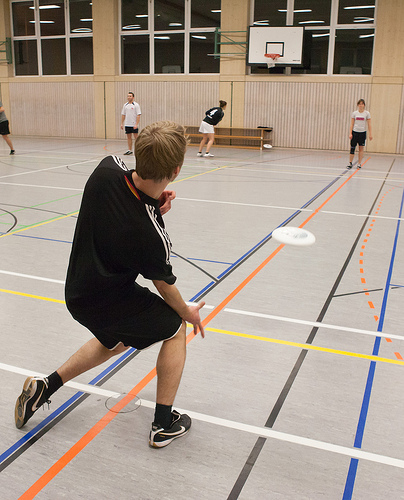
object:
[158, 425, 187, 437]
logo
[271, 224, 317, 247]
frisbee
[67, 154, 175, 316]
shirt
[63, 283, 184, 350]
shorts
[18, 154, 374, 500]
line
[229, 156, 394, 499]
line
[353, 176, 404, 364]
line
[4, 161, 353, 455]
line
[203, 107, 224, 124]
shirt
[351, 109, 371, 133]
top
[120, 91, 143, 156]
man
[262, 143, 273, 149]
frisbee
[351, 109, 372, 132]
shirt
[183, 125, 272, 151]
bench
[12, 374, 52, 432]
shoes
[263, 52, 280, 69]
hoop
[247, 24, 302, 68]
basketball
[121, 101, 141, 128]
shirt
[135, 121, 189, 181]
hair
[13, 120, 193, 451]
guy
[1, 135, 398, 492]
court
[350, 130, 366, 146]
shorts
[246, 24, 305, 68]
backboard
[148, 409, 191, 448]
shoe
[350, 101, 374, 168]
woman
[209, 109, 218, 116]
design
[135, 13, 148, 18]
light